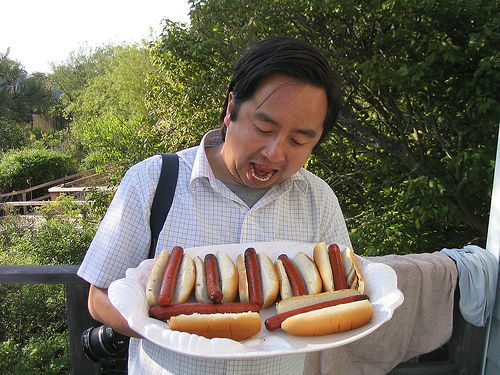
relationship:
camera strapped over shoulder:
[76, 325, 132, 363] [123, 144, 201, 238]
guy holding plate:
[75, 38, 352, 373] [106, 240, 405, 360]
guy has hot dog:
[75, 38, 352, 373] [264, 292, 372, 332]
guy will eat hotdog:
[75, 38, 352, 373] [320, 229, 363, 292]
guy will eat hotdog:
[75, 38, 352, 373] [267, 285, 368, 330]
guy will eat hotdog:
[75, 38, 352, 373] [142, 291, 262, 331]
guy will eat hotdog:
[75, 38, 352, 373] [146, 236, 189, 306]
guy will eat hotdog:
[75, 38, 352, 373] [238, 235, 268, 300]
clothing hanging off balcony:
[441, 244, 500, 328] [11, 248, 496, 371]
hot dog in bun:
[153, 224, 383, 342] [280, 287, 372, 338]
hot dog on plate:
[264, 292, 372, 332] [104, 237, 410, 363]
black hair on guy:
[216, 37, 342, 146] [68, 38, 358, 373]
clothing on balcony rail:
[381, 242, 498, 369] [2, 251, 487, 373]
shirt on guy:
[192, 193, 226, 225] [75, 38, 352, 373]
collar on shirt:
[194, 122, 316, 204] [66, 132, 398, 373]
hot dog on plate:
[148, 301, 261, 319] [106, 240, 405, 360]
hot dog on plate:
[245, 246, 264, 307] [106, 240, 405, 360]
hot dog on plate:
[327, 244, 349, 291] [106, 240, 405, 360]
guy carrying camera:
[75, 38, 352, 373] [77, 298, 129, 368]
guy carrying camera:
[75, 38, 352, 373] [69, 312, 129, 361]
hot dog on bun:
[148, 301, 261, 319] [166, 310, 265, 343]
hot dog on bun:
[264, 292, 372, 332] [276, 286, 373, 336]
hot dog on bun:
[148, 301, 261, 319] [173, 312, 264, 339]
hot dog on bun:
[157, 246, 184, 305] [145, 246, 193, 300]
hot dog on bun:
[245, 246, 264, 307] [238, 252, 277, 306]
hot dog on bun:
[278, 253, 307, 296] [284, 301, 396, 326]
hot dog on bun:
[157, 246, 184, 305] [148, 243, 164, 300]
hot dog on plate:
[157, 246, 184, 305] [104, 237, 410, 363]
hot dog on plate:
[203, 253, 223, 303] [104, 237, 410, 363]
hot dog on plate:
[245, 246, 264, 307] [104, 237, 410, 363]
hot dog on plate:
[278, 253, 307, 296] [104, 237, 410, 363]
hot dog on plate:
[263, 285, 376, 340] [104, 237, 410, 363]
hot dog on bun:
[157, 246, 184, 305] [141, 248, 195, 304]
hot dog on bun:
[203, 249, 224, 304] [196, 251, 240, 301]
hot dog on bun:
[245, 245, 267, 310] [232, 249, 283, 306]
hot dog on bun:
[279, 251, 307, 299] [275, 253, 324, 298]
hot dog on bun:
[325, 244, 350, 291] [313, 237, 366, 294]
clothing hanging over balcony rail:
[397, 252, 498, 353] [2, 251, 487, 373]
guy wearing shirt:
[75, 38, 352, 373] [75, 126, 353, 374]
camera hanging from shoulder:
[76, 325, 132, 363] [141, 144, 193, 254]